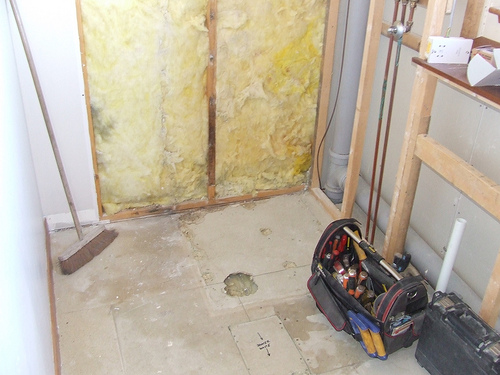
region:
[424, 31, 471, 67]
white plastic outlet box on shelf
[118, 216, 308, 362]
dirty tiles on floor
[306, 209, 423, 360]
used toolbox filled with tools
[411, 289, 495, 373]
hard plastic toolbox on side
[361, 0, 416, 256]
two thin copper tubes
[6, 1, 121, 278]
old short-hair wooden broom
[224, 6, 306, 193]
exposed insulation on wall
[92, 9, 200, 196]
dirty yellow fiberglass insulation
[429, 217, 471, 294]
white pvc pipe sticking up from ground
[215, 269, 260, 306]
patched drain hole in floor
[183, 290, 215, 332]
part of a floor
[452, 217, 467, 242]
part of a plastic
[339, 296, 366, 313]
edge of a bag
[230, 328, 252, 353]
part of a floor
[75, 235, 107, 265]
part of a broom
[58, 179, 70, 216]
part of a handle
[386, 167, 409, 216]
part of a stand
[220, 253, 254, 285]
part of a surface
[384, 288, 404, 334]
edge of a bag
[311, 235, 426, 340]
this is a tool bag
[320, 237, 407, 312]
the bag is open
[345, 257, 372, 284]
tools are in the bag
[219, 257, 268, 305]
the floor is cracky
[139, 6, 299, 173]
the wall is old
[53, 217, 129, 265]
this is a broom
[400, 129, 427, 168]
this is a wood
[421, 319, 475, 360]
this is a suitcase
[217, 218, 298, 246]
the floor is old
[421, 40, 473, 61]
this is a socket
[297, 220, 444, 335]
the bag is full of tools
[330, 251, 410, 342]
the bag is full of tools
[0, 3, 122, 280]
push broom leaning in corner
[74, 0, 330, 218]
Exposed insulation in the back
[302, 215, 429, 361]
open handle tool bag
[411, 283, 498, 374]
black locking tool box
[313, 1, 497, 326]
plumbing is behind the wood frames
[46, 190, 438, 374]
the flooring is concrete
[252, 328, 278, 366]
There is writing on the floor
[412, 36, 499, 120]
counter top above tool bags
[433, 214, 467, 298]
white PVC tubing coming out of the ground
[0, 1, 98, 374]
back and left wall are light blue